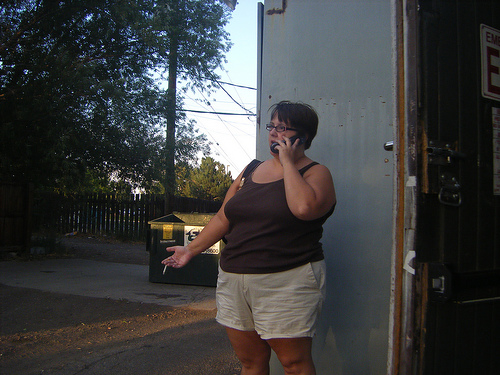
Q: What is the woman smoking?
A: A cigarette.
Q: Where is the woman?
A: Outside a door.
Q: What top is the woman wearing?
A: A tanktop.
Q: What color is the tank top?
A: Brown.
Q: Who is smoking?
A: The woman.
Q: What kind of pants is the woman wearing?
A: Shorts.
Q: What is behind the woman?
A: A dumpster.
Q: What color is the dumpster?
A: Green.